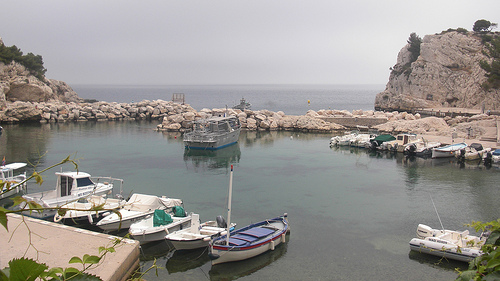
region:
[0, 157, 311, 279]
A series of boats lined up on the water.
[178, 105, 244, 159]
A large tug boat.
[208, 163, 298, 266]
A boat with a blue deck.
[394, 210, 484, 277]
A small boat off to the side.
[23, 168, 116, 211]
A white boat with a cabin.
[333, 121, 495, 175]
A line of smaller boats.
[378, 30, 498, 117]
A large cliff face.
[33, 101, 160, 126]
A reef made of rocks.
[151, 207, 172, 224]
A green tarp covering a boat.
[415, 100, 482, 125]
A wooden platform at the base of a cliff.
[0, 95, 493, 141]
A stond breakwater in front of harbor.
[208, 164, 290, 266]
Blue and white boat with a mast.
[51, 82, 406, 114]
Open ocean beyond rocks.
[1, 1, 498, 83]
The sky is gray.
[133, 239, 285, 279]
Three boats reflected in water.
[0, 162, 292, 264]
Seven boats parked alongside each other.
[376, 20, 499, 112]
White rock with green bushes.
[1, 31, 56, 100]
Green bushed on top of white rock.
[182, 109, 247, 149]
Gray boat with blue bottom.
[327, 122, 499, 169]
Several boats parked near the shore.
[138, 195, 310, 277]
boats on the water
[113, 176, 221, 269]
boats on the water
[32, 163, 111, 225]
boats on the water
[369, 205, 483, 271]
boats on the water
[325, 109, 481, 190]
boats on the water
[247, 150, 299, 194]
the water is calm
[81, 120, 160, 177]
the water is calm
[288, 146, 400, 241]
the water is calm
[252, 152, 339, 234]
the water is calm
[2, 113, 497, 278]
water area for boat parking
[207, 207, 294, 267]
red white blue boat in foreground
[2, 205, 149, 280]
corner of building roof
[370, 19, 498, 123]
rocky faced cliff in distance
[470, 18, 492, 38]
green tree atop cliff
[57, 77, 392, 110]
ocean water in distance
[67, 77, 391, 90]
horizon beyond ocean water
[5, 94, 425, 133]
rock break wall barrier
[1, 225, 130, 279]
ivy on building roof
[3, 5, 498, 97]
hazy gray cloudy sky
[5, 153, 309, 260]
Boats lined up in a row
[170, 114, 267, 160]
This boat is alone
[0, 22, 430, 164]
Rocks lined in the water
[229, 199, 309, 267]
This boat is blue and red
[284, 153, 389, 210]
The water is calm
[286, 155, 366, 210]
This water is not see-through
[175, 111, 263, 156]
A silver and blue boat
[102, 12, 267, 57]
It is not sunny outside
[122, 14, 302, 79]
The sky is cloudy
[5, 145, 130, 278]
A tree in the corner